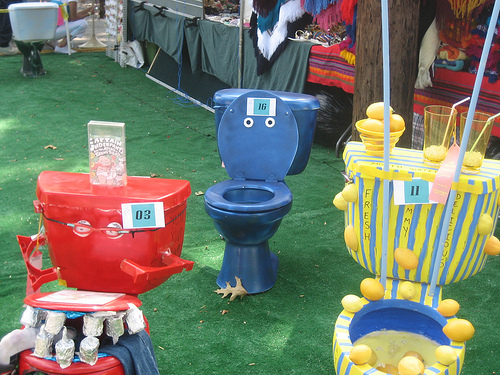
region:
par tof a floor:
[297, 308, 341, 349]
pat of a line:
[242, 284, 281, 332]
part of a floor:
[279, 328, 290, 340]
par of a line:
[288, 323, 309, 348]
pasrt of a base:
[224, 273, 256, 308]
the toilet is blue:
[198, 85, 293, 312]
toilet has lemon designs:
[339, 137, 480, 373]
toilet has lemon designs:
[314, 90, 434, 362]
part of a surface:
[317, 289, 333, 299]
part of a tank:
[86, 211, 106, 237]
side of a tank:
[252, 273, 288, 295]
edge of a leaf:
[288, 319, 289, 324]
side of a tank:
[269, 294, 279, 309]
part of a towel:
[114, 313, 146, 339]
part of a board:
[390, 237, 402, 244]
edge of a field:
[330, 257, 340, 270]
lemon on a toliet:
[341, 183, 361, 204]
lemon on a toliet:
[331, 190, 347, 212]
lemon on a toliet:
[342, 223, 359, 256]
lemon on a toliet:
[393, 246, 418, 271]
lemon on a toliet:
[477, 208, 492, 235]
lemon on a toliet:
[486, 235, 498, 256]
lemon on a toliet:
[358, 271, 381, 302]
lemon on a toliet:
[394, 278, 415, 296]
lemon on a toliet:
[436, 290, 459, 315]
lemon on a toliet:
[441, 317, 476, 344]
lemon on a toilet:
[341, 184, 358, 204]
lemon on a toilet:
[333, 192, 348, 217]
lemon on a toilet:
[341, 221, 359, 251]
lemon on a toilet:
[391, 244, 419, 269]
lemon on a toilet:
[398, 276, 414, 301]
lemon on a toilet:
[358, 278, 385, 299]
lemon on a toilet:
[341, 295, 363, 313]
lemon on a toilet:
[349, 342, 371, 364]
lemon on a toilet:
[436, 296, 460, 316]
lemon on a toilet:
[440, 317, 473, 346]